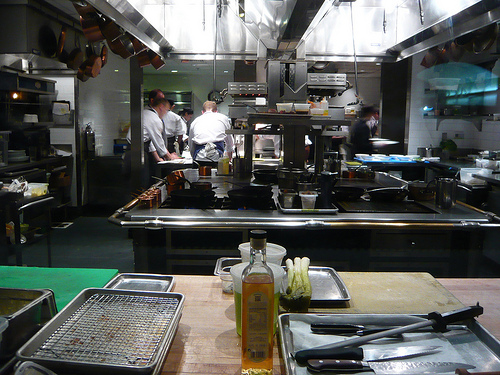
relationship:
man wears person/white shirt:
[114, 85, 187, 171] [137, 97, 172, 159]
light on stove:
[10, 92, 19, 101] [4, 68, 72, 231]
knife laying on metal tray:
[308, 318, 471, 338] [114, 271, 178, 292]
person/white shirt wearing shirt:
[137, 97, 172, 159] [124, 106, 170, 157]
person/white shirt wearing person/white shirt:
[187, 100, 232, 164] [187, 100, 232, 164]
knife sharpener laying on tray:
[294, 301, 483, 357] [279, 313, 499, 373]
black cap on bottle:
[240, 227, 270, 237] [241, 225, 274, 372]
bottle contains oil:
[241, 225, 274, 372] [233, 225, 282, 372]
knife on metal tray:
[301, 356, 480, 373] [114, 271, 178, 292]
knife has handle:
[301, 356, 480, 373] [290, 343, 369, 367]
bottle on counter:
[241, 225, 274, 372] [0, 257, 499, 373]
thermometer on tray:
[307, 302, 485, 349] [279, 313, 499, 373]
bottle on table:
[241, 225, 274, 372] [175, 310, 237, 374]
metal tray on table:
[114, 271, 178, 292] [342, 274, 467, 311]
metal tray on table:
[61, 283, 183, 374] [183, 295, 233, 369]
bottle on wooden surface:
[241, 225, 274, 372] [159, 268, 498, 373]